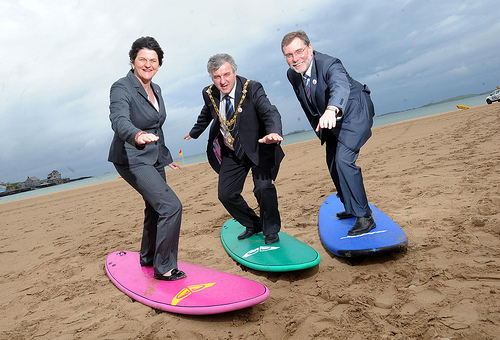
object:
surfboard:
[105, 250, 270, 315]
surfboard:
[317, 192, 406, 257]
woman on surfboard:
[107, 37, 186, 282]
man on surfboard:
[184, 53, 281, 244]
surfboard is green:
[221, 217, 320, 272]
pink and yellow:
[105, 251, 271, 316]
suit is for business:
[107, 70, 182, 274]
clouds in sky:
[0, 0, 497, 192]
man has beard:
[282, 30, 375, 235]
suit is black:
[189, 75, 285, 235]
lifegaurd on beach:
[485, 87, 498, 104]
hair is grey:
[207, 53, 236, 73]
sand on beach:
[0, 103, 499, 339]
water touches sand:
[0, 89, 499, 205]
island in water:
[1, 169, 95, 199]